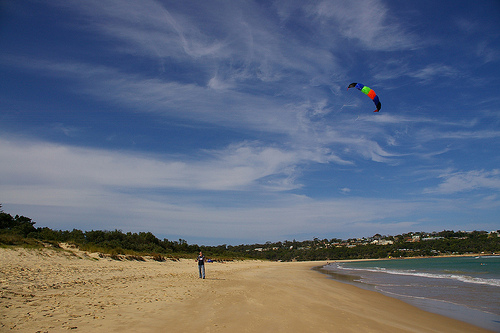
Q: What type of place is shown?
A: It is a beach.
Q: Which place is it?
A: It is a beach.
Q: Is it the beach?
A: Yes, it is the beach.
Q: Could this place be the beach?
A: Yes, it is the beach.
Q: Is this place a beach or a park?
A: It is a beach.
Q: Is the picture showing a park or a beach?
A: It is showing a beach.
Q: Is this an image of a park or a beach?
A: It is showing a beach.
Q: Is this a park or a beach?
A: It is a beach.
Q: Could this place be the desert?
A: No, it is the beach.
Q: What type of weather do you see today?
A: It is cloudy.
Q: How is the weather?
A: It is cloudy.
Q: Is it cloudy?
A: Yes, it is cloudy.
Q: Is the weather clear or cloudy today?
A: It is cloudy.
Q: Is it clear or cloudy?
A: It is cloudy.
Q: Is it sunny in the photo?
A: No, it is cloudy.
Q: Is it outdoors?
A: Yes, it is outdoors.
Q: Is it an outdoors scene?
A: Yes, it is outdoors.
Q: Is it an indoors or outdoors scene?
A: It is outdoors.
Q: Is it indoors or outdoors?
A: It is outdoors.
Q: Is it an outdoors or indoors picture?
A: It is outdoors.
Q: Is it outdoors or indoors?
A: It is outdoors.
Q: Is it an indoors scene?
A: No, it is outdoors.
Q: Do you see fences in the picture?
A: No, there are no fences.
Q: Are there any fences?
A: No, there are no fences.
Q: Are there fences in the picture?
A: No, there are no fences.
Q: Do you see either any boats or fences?
A: No, there are no fences or boats.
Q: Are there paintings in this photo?
A: No, there are no paintings.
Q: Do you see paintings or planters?
A: No, there are no paintings or planters.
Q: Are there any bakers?
A: No, there are no bakers.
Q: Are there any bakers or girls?
A: No, there are no bakers or girls.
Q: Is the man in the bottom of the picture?
A: Yes, the man is in the bottom of the image.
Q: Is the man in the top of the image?
A: No, the man is in the bottom of the image.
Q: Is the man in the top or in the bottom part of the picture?
A: The man is in the bottom of the image.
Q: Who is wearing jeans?
A: The man is wearing jeans.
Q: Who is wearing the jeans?
A: The man is wearing jeans.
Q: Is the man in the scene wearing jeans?
A: Yes, the man is wearing jeans.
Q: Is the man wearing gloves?
A: No, the man is wearing jeans.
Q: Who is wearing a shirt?
A: The man is wearing a shirt.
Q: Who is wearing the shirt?
A: The man is wearing a shirt.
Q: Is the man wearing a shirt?
A: Yes, the man is wearing a shirt.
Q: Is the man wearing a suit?
A: No, the man is wearing a shirt.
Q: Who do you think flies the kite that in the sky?
A: The man flies the kite.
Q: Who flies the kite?
A: The man flies the kite.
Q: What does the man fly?
A: The man flies the kite.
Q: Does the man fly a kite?
A: Yes, the man flies a kite.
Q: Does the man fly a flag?
A: No, the man flies a kite.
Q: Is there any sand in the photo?
A: Yes, there is sand.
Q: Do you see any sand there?
A: Yes, there is sand.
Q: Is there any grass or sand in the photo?
A: Yes, there is sand.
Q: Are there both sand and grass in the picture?
A: No, there is sand but no grass.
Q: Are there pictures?
A: No, there are no pictures.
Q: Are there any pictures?
A: No, there are no pictures.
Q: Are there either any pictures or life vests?
A: No, there are no pictures or life vests.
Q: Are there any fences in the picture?
A: No, there are no fences.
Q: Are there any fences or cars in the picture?
A: No, there are no fences or cars.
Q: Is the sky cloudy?
A: Yes, the sky is cloudy.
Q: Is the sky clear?
A: No, the sky is cloudy.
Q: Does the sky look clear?
A: No, the sky is cloudy.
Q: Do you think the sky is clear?
A: No, the sky is cloudy.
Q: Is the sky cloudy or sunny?
A: The sky is cloudy.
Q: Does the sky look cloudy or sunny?
A: The sky is cloudy.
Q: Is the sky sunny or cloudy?
A: The sky is cloudy.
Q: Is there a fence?
A: No, there are no fences.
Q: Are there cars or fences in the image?
A: No, there are no fences or cars.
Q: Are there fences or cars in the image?
A: No, there are no fences or cars.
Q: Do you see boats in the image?
A: No, there are no boats.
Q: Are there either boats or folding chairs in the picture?
A: No, there are no boats or folding chairs.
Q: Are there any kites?
A: Yes, there is a kite.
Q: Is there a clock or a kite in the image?
A: Yes, there is a kite.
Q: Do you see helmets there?
A: No, there are no helmets.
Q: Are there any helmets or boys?
A: No, there are no helmets or boys.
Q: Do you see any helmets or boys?
A: No, there are no helmets or boys.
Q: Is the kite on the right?
A: Yes, the kite is on the right of the image.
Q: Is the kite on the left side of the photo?
A: No, the kite is on the right of the image.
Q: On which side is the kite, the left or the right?
A: The kite is on the right of the image.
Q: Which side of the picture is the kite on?
A: The kite is on the right of the image.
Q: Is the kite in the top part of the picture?
A: Yes, the kite is in the top of the image.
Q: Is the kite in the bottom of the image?
A: No, the kite is in the top of the image.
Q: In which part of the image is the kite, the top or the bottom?
A: The kite is in the top of the image.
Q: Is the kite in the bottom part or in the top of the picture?
A: The kite is in the top of the image.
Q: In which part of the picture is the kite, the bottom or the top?
A: The kite is in the top of the image.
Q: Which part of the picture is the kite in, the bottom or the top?
A: The kite is in the top of the image.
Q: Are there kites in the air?
A: Yes, there is a kite in the air.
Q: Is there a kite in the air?
A: Yes, there is a kite in the air.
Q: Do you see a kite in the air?
A: Yes, there is a kite in the air.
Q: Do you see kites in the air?
A: Yes, there is a kite in the air.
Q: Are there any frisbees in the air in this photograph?
A: No, there is a kite in the air.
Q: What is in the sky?
A: The kite is in the sky.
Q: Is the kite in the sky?
A: Yes, the kite is in the sky.